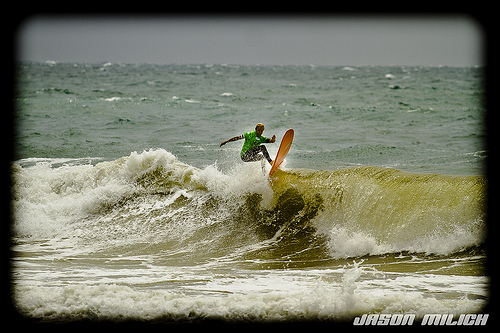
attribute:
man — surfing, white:
[224, 122, 280, 158]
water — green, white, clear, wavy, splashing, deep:
[56, 84, 163, 212]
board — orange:
[276, 123, 317, 168]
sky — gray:
[77, 11, 386, 73]